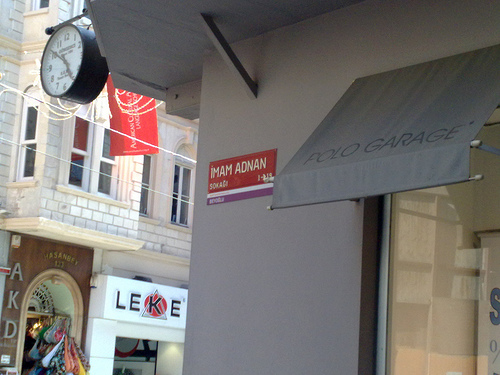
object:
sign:
[204, 144, 277, 206]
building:
[83, 1, 500, 375]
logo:
[302, 122, 476, 171]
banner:
[105, 73, 160, 158]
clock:
[38, 22, 108, 105]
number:
[64, 33, 71, 42]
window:
[374, 126, 499, 375]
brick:
[69, 206, 81, 216]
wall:
[194, 228, 339, 375]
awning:
[268, 43, 499, 209]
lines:
[0, 85, 195, 163]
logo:
[114, 286, 183, 318]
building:
[0, 0, 196, 374]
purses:
[76, 344, 90, 375]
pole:
[46, 10, 89, 35]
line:
[206, 182, 274, 199]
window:
[16, 103, 39, 175]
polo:
[304, 141, 362, 169]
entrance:
[83, 273, 187, 375]